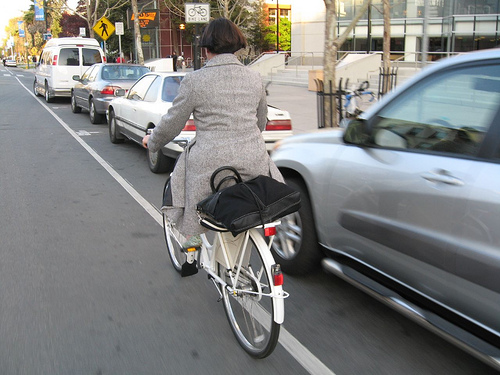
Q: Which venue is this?
A: This is a street.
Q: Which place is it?
A: It is a street.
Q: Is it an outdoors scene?
A: Yes, it is outdoors.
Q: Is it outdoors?
A: Yes, it is outdoors.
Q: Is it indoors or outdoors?
A: It is outdoors.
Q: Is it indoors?
A: No, it is outdoors.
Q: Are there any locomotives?
A: No, there are no locomotives.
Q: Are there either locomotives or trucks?
A: No, there are no locomotives or trucks.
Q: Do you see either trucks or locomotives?
A: No, there are no locomotives or trucks.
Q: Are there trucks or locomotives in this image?
A: No, there are no locomotives or trucks.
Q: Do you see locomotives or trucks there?
A: No, there are no locomotives or trucks.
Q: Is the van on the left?
A: Yes, the van is on the left of the image.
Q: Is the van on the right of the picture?
A: No, the van is on the left of the image.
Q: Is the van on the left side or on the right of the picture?
A: The van is on the left of the image.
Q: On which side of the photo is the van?
A: The van is on the left of the image.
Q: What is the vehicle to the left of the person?
A: The vehicle is a van.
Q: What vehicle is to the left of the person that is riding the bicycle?
A: The vehicle is a van.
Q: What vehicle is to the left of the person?
A: The vehicle is a van.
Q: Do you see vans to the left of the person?
A: Yes, there is a van to the left of the person.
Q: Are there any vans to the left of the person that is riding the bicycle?
A: Yes, there is a van to the left of the person.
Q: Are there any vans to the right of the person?
A: No, the van is to the left of the person.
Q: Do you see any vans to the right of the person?
A: No, the van is to the left of the person.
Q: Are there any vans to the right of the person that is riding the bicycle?
A: No, the van is to the left of the person.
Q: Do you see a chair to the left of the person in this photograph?
A: No, there is a van to the left of the person.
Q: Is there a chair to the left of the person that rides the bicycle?
A: No, there is a van to the left of the person.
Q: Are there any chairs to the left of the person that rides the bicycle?
A: No, there is a van to the left of the person.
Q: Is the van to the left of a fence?
A: No, the van is to the left of a person.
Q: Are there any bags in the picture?
A: Yes, there is a bag.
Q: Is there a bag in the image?
A: Yes, there is a bag.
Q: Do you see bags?
A: Yes, there is a bag.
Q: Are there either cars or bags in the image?
A: Yes, there is a bag.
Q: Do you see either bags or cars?
A: Yes, there is a bag.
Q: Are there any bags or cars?
A: Yes, there is a bag.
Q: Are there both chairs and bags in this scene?
A: No, there is a bag but no chairs.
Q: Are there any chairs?
A: No, there are no chairs.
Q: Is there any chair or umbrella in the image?
A: No, there are no chairs or umbrellas.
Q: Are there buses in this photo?
A: No, there are no buses.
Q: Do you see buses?
A: No, there are no buses.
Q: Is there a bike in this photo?
A: Yes, there is a bike.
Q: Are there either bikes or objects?
A: Yes, there is a bike.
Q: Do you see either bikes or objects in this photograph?
A: Yes, there is a bike.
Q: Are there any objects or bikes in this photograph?
A: Yes, there is a bike.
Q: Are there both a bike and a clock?
A: No, there is a bike but no clocks.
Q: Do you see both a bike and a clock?
A: No, there is a bike but no clocks.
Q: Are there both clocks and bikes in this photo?
A: No, there is a bike but no clocks.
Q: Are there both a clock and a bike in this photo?
A: No, there is a bike but no clocks.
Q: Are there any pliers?
A: No, there are no pliers.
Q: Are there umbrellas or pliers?
A: No, there are no pliers or umbrellas.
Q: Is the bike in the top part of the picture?
A: Yes, the bike is in the top of the image.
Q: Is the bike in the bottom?
A: No, the bike is in the top of the image.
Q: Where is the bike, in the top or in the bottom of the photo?
A: The bike is in the top of the image.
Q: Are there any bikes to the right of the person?
A: Yes, there is a bike to the right of the person.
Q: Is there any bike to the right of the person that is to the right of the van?
A: Yes, there is a bike to the right of the person.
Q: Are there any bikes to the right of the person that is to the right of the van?
A: Yes, there is a bike to the right of the person.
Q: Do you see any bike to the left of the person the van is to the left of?
A: No, the bike is to the right of the person.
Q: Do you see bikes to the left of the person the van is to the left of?
A: No, the bike is to the right of the person.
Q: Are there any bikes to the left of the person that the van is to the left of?
A: No, the bike is to the right of the person.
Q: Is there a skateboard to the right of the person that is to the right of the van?
A: No, there is a bike to the right of the person.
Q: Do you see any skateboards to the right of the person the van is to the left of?
A: No, there is a bike to the right of the person.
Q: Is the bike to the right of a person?
A: Yes, the bike is to the right of a person.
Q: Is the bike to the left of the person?
A: No, the bike is to the right of the person.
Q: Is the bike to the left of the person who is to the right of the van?
A: No, the bike is to the right of the person.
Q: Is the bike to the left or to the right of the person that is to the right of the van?
A: The bike is to the right of the person.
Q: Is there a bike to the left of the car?
A: No, the bike is to the right of the car.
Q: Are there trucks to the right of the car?
A: No, there is a bike to the right of the car.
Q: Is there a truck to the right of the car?
A: No, there is a bike to the right of the car.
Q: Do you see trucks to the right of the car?
A: No, there is a bike to the right of the car.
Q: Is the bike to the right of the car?
A: Yes, the bike is to the right of the car.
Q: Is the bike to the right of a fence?
A: No, the bike is to the right of the car.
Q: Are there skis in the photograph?
A: No, there are no skis.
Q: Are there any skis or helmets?
A: No, there are no skis or helmets.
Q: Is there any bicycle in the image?
A: Yes, there is a bicycle.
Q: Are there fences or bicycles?
A: Yes, there is a bicycle.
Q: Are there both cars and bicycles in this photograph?
A: Yes, there are both a bicycle and a car.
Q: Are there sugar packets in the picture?
A: No, there are no sugar packets.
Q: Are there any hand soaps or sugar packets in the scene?
A: No, there are no sugar packets or hand soaps.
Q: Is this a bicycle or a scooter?
A: This is a bicycle.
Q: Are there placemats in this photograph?
A: No, there are no placemats.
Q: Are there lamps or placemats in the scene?
A: No, there are no placemats or lamps.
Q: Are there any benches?
A: No, there are no benches.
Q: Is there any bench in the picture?
A: No, there are no benches.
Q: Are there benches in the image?
A: No, there are no benches.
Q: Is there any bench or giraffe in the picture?
A: No, there are no benches or giraffes.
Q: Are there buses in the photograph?
A: No, there are no buses.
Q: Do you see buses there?
A: No, there are no buses.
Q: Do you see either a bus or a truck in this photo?
A: No, there are no buses or trucks.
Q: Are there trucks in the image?
A: No, there are no trucks.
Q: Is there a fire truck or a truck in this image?
A: No, there are no trucks or fire trucks.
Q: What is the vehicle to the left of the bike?
A: The vehicle is a car.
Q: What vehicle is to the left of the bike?
A: The vehicle is a car.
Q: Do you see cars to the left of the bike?
A: Yes, there is a car to the left of the bike.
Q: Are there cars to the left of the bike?
A: Yes, there is a car to the left of the bike.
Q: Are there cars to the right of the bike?
A: No, the car is to the left of the bike.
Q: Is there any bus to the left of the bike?
A: No, there is a car to the left of the bike.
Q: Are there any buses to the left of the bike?
A: No, there is a car to the left of the bike.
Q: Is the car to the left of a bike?
A: Yes, the car is to the left of a bike.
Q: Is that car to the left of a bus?
A: No, the car is to the left of a bike.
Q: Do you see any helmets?
A: No, there are no helmets.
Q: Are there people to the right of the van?
A: Yes, there is a person to the right of the van.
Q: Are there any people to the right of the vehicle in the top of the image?
A: Yes, there is a person to the right of the van.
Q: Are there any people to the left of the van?
A: No, the person is to the right of the van.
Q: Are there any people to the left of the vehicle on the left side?
A: No, the person is to the right of the van.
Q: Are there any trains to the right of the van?
A: No, there is a person to the right of the van.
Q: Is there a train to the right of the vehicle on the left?
A: No, there is a person to the right of the van.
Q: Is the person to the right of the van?
A: Yes, the person is to the right of the van.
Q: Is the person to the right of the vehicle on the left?
A: Yes, the person is to the right of the van.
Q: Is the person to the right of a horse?
A: No, the person is to the right of the van.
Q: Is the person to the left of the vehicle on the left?
A: No, the person is to the right of the van.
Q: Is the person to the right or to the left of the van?
A: The person is to the right of the van.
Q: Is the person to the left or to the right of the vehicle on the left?
A: The person is to the right of the van.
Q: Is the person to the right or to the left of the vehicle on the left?
A: The person is to the right of the van.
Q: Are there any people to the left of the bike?
A: Yes, there is a person to the left of the bike.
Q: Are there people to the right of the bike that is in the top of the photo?
A: No, the person is to the left of the bike.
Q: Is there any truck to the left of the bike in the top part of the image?
A: No, there is a person to the left of the bike.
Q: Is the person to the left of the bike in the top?
A: Yes, the person is to the left of the bike.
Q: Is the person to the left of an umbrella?
A: No, the person is to the left of the bike.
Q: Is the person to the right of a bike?
A: No, the person is to the left of a bike.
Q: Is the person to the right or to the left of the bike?
A: The person is to the left of the bike.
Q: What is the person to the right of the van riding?
A: The person is riding the bicycle.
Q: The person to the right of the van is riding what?
A: The person is riding the bicycle.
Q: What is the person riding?
A: The person is riding the bicycle.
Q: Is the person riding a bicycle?
A: Yes, the person is riding a bicycle.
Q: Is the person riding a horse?
A: No, the person is riding a bicycle.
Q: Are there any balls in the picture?
A: No, there are no balls.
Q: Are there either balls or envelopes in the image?
A: No, there are no balls or envelopes.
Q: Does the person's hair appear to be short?
A: Yes, the hair is short.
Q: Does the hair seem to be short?
A: Yes, the hair is short.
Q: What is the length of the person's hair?
A: The hair is short.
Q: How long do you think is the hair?
A: The hair is short.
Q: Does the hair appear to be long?
A: No, the hair is short.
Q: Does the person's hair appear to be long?
A: No, the hair is short.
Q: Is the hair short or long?
A: The hair is short.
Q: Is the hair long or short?
A: The hair is short.